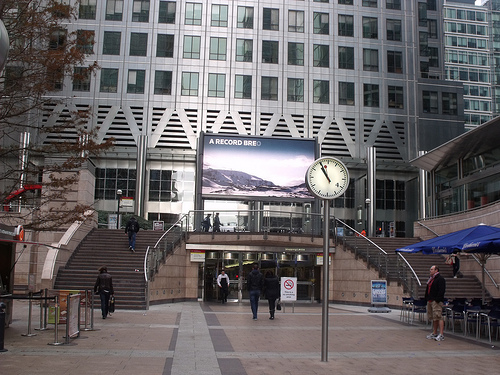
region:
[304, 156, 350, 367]
clock on top of a silver pole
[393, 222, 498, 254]
two blue umbrellas over tables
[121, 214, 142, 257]
person walking up a staircase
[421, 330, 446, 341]
man wearing white sneakers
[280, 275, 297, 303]
no smoking sign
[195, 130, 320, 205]
mountains on a billboard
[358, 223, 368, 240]
person wearing a bright orange jacket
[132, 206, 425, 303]
glass and metal railing on the inside of the staircase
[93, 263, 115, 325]
person carrying a black briefcase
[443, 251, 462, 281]
person walking down the stairs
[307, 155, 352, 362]
a tall clock pointing at 10:55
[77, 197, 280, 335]
people walking by the place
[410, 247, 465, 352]
a man in a black sweat shirt and shorts is waiting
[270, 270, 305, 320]
a no smoking sign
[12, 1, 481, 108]
a building with lots of windows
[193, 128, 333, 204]
a large advertisment logo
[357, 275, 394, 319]
small advertisment logo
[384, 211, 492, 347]
seats with a large blue umbrella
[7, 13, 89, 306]
a tree with no leaves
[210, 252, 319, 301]
doors to the building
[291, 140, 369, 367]
Clock in the middle of the sidewalk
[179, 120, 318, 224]
Big sign in front of building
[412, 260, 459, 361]
Man standing with hands in pocket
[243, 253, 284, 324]
Two people walking closely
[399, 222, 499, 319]
Big blue umberella over chairs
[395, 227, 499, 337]
Chairs underneath blue umberella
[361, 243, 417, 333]
Small sign beside stairs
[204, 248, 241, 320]
Someone coming out of building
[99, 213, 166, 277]
Someone walking up the stairs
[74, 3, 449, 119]
Multiple windows on building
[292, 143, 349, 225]
Clock on top of a pole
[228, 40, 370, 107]
Windows on side of building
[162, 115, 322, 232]
Billboard in front of the building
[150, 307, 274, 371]
The ground is covered in tiles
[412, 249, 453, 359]
Man standing beside the chairs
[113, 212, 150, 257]
Person walking up the stairs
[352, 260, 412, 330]
Sign sitting beside staircase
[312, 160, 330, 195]
Hands on the clock are black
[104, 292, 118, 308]
The woman is carrying a purse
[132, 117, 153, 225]
Large metal pole in front of building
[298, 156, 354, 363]
Clock on a pole.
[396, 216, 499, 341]
Blue covered tent.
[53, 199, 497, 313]
Stairs going up and down.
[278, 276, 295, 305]
No smoking sign.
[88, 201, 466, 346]
People in the area.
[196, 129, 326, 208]
Advertising billboard up high.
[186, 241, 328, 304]
Door going under the stairs.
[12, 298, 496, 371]
Brick walkway up to stairs.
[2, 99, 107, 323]
Trees off to the side.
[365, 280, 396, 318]
Sign on the ground.